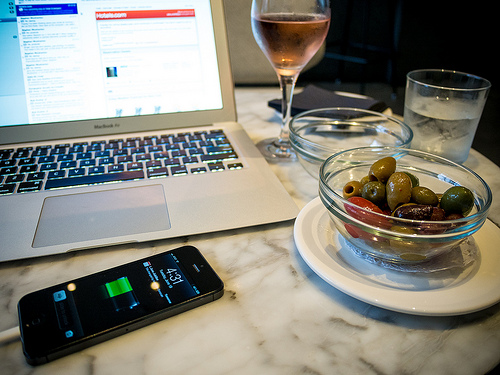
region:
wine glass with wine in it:
[250, 0, 330, 163]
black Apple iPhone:
[17, 244, 224, 364]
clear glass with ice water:
[404, 69, 491, 162]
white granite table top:
[1, 87, 495, 366]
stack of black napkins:
[268, 83, 388, 127]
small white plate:
[293, 193, 498, 313]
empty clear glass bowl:
[288, 106, 412, 178]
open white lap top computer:
[0, 2, 296, 261]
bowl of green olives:
[321, 145, 491, 270]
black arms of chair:
[303, 41, 396, 107]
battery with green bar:
[96, 269, 141, 320]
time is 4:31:
[165, 256, 188, 295]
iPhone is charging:
[22, 245, 229, 349]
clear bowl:
[313, 157, 481, 265]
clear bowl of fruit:
[336, 142, 476, 266]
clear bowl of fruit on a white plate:
[311, 154, 499, 316]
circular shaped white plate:
[299, 235, 496, 312]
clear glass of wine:
[247, 0, 308, 157]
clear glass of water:
[407, 70, 489, 153]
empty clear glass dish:
[298, 105, 404, 158]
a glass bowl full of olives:
[317, 146, 494, 271]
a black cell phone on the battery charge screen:
[16, 242, 226, 366]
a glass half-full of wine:
[248, 1, 330, 161]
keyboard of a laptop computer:
[1, 130, 246, 197]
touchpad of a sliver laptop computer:
[33, 182, 173, 252]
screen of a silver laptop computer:
[1, 1, 225, 128]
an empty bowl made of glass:
[291, 102, 408, 179]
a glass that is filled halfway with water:
[401, 69, 492, 166]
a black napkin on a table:
[266, 84, 387, 124]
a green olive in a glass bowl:
[441, 181, 475, 218]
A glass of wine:
[251, 0, 330, 165]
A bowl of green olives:
[316, 147, 493, 267]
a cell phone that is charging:
[15, 244, 227, 365]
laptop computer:
[1, 2, 247, 229]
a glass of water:
[405, 68, 488, 166]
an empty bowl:
[289, 106, 414, 173]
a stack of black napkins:
[279, 87, 384, 117]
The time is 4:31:
[164, 265, 184, 287]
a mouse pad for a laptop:
[32, 185, 175, 245]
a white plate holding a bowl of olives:
[295, 191, 497, 314]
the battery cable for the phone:
[4, 323, 31, 351]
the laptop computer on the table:
[3, 4, 303, 245]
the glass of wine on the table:
[249, 3, 319, 155]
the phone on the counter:
[11, 256, 229, 341]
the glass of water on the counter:
[410, 75, 482, 172]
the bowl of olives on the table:
[328, 143, 480, 280]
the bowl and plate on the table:
[323, 144, 480, 302]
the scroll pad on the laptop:
[39, 195, 188, 245]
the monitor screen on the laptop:
[6, 1, 233, 116]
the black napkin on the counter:
[271, 85, 376, 129]